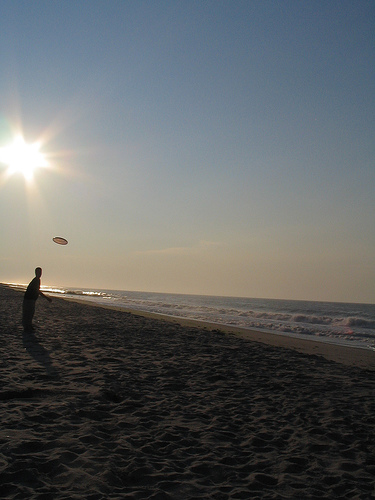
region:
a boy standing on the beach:
[21, 265, 49, 327]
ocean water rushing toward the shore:
[8, 275, 374, 346]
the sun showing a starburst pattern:
[1, 98, 86, 225]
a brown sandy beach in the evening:
[1, 283, 374, 498]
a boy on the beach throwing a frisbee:
[1, 235, 77, 331]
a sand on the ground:
[4, 285, 374, 496]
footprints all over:
[5, 353, 367, 496]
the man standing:
[21, 264, 45, 350]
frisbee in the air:
[50, 232, 68, 248]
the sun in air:
[1, 92, 91, 216]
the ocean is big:
[4, 279, 374, 343]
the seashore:
[49, 291, 369, 351]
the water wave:
[54, 284, 114, 297]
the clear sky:
[0, 89, 366, 302]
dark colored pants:
[19, 295, 35, 331]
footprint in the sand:
[159, 480, 191, 493]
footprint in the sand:
[168, 462, 184, 474]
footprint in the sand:
[252, 471, 274, 485]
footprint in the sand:
[284, 481, 309, 489]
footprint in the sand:
[252, 444, 273, 455]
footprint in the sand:
[14, 441, 44, 454]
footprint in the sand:
[8, 470, 48, 491]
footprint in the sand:
[102, 388, 122, 401]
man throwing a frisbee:
[24, 261, 58, 318]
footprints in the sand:
[152, 367, 269, 452]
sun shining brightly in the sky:
[8, 130, 48, 175]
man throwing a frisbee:
[20, 221, 84, 338]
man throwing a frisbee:
[21, 228, 78, 333]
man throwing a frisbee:
[19, 227, 87, 335]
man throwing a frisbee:
[15, 233, 96, 340]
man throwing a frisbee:
[11, 230, 72, 344]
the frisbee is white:
[50, 232, 72, 250]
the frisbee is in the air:
[44, 223, 76, 257]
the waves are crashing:
[137, 287, 347, 338]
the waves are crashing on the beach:
[74, 276, 366, 402]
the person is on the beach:
[20, 265, 52, 346]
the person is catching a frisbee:
[21, 226, 75, 350]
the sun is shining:
[8, 125, 64, 198]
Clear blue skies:
[164, 96, 275, 160]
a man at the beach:
[7, 247, 55, 339]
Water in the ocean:
[152, 283, 290, 323]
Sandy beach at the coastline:
[122, 382, 282, 486]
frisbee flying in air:
[52, 236, 66, 245]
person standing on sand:
[19, 265, 54, 335]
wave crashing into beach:
[6, 282, 118, 297]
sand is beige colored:
[0, 283, 373, 498]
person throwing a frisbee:
[18, 265, 50, 331]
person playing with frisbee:
[23, 267, 53, 329]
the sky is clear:
[173, 152, 247, 202]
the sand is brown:
[170, 373, 247, 419]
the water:
[317, 308, 367, 327]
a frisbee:
[50, 231, 69, 246]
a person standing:
[18, 261, 53, 324]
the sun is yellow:
[6, 131, 41, 185]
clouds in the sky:
[162, 236, 223, 269]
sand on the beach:
[307, 338, 340, 355]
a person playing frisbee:
[13, 228, 75, 334]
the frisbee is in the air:
[48, 229, 70, 249]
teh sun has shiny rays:
[2, 121, 75, 213]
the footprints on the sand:
[42, 325, 272, 469]